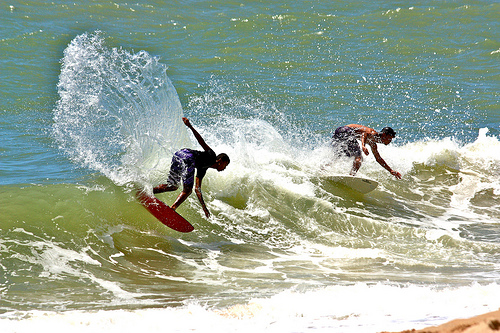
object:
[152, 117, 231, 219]
surfer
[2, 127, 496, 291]
wave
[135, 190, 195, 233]
surfboard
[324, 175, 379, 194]
surfboard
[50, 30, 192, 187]
splash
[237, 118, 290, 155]
splash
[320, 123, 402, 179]
surfer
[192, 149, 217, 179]
shirt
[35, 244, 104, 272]
foam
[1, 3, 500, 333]
water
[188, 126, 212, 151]
arm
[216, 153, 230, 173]
head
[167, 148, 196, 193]
pants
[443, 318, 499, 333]
sand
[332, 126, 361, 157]
shorts